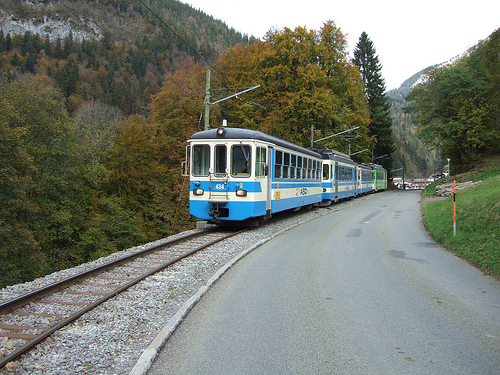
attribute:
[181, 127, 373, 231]
train — blue, white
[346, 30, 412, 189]
tree — tall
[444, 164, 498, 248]
pole — orange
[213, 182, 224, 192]
number — white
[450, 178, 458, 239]
pole — orange, black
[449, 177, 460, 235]
pole — orange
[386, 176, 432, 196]
town — small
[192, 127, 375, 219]
train — blue, white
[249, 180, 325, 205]
stripes — white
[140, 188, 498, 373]
street — gray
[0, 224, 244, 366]
tracks — steel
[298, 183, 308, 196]
writing — blue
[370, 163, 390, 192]
car — green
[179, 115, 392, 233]
train — blue, white